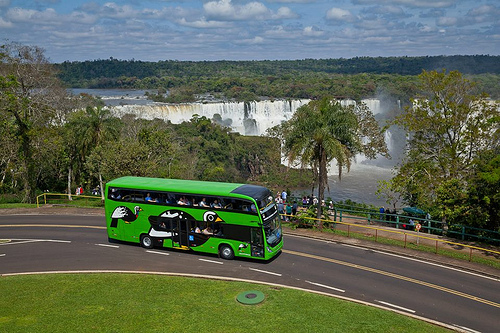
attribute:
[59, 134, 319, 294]
bus — tour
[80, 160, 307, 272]
bus — tour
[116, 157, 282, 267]
bus — tour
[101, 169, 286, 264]
bus — tour, green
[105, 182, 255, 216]
story — second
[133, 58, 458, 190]
lake — large, water